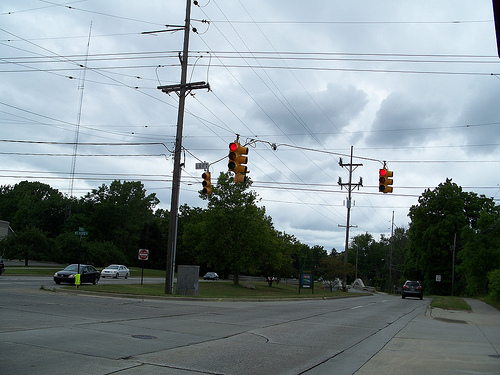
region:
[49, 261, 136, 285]
HERE IS TWO CARS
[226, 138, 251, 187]
THIS IS A RED LIGHT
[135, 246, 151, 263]
THIS IS A DO NOT ENTER SIGN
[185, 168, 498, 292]
THESE ARE GREEN TREES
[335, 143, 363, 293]
THIS IS A TELEPHONE POLE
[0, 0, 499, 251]
THESE ARE DARK CLOUDS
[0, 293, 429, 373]
THIS IS A SIDEWALK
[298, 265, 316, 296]
THIS IS A SIGN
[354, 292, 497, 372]
THIS IS A SIDEWALK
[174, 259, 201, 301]
THIS A POWER BOX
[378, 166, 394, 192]
traffic light with the red light on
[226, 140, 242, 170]
other traffic light with the red light on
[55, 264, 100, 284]
black car coming into the intersection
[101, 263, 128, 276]
white car coming to the intersection behind the black car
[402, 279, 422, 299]
dark colored van or SUV driving away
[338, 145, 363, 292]
telephone pole in the island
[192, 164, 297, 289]
tree that stands in the island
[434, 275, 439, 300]
white traffic sight on the curb next to the street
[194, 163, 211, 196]
traffic light for a protected left turn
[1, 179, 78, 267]
large round tree in the park next to the street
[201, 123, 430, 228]
Group of yellow street lights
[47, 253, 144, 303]
Two cars driving down the road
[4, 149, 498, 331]
Group of trees in the distance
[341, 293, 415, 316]
White lines in the middle of the road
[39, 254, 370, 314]
Area of green grass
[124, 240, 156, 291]
Red and white sign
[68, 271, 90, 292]
Yellow flyer in the grass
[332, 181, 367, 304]
Tall skinny brown electricity pole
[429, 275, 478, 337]
Area of grass in the sidewalk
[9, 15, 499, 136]
Black electricity wires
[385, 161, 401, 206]
yellow traffic light signal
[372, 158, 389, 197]
yellow traffic light signal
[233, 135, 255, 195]
yellow traffic light signal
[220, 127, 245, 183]
yellow traffic light signal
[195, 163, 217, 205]
yellow traffic light signal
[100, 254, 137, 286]
car driving on road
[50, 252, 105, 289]
car driving on road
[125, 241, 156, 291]
traffic sign on post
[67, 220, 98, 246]
name street sign on post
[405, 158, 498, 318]
tall green leafy tree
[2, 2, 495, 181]
the sky is cloudy and looks like a storm is coming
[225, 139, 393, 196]
the traffic lights are red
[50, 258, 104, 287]
a black car is stopped at the red light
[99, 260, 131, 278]
a white car approaches the intersection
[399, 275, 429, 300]
a black car drives away from us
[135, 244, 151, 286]
a "do not enter" sign to protect opposing traffic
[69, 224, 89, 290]
a street sign is posted at the curb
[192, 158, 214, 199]
this traffic signal is for cars turning left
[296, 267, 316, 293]
some kind of sign for passing cars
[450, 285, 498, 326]
no one is walking along this sidewalk